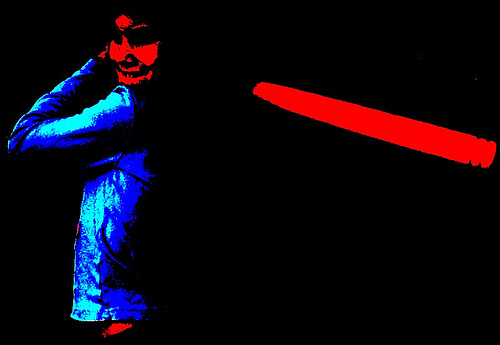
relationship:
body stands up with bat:
[7, 11, 174, 336] [258, 66, 449, 177]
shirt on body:
[6, 56, 165, 324] [8, 11, 174, 336]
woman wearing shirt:
[2, 13, 179, 337] [9, 72, 153, 320]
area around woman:
[6, 6, 496, 337] [3, 7, 215, 341]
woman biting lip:
[2, 4, 180, 339] [115, 50, 158, 89]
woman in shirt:
[2, 4, 180, 339] [6, 56, 165, 324]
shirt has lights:
[6, 56, 165, 324] [80, 190, 104, 320]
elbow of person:
[73, 121, 88, 141] [11, 6, 172, 342]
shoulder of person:
[113, 77, 148, 126] [11, 6, 172, 342]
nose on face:
[116, 52, 142, 68] [99, 8, 172, 83]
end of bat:
[470, 135, 493, 168] [191, 58, 499, 163]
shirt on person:
[6, 55, 163, 341] [11, 6, 172, 342]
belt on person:
[58, 300, 154, 342] [38, 15, 247, 275]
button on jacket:
[68, 212, 83, 250] [11, 58, 271, 320]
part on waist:
[95, 314, 136, 341] [80, 307, 160, 340]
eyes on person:
[102, 22, 167, 52] [12, 10, 221, 332]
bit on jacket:
[71, 220, 86, 237] [10, 56, 192, 326]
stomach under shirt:
[50, 287, 150, 332] [92, 319, 130, 338]